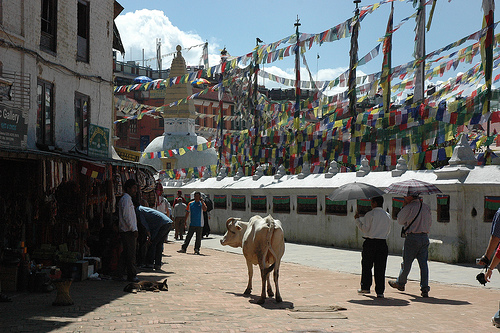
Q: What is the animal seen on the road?
A: A white cow.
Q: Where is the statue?
A: By the roadside on a high pedestal.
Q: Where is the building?
A: On left side of the road.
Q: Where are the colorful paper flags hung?
A: By the roadside near the statue.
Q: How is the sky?
A: Blue sky has white clouds.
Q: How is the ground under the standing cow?
A: Paved with brown tiles.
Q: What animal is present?
A: Cow.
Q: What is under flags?
A: White building.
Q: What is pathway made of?
A: Bricks.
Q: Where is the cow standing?
A: The street.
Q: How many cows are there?
A: One.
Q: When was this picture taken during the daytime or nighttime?
A: Daytime.